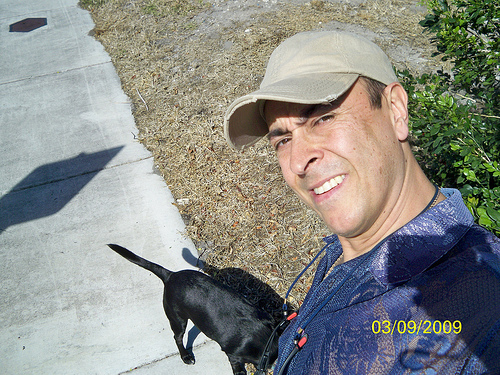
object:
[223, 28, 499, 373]
man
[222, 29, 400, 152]
hat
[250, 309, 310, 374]
sunglasses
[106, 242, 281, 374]
dog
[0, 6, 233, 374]
street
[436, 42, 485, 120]
leaves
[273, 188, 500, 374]
shirt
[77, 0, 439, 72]
grass